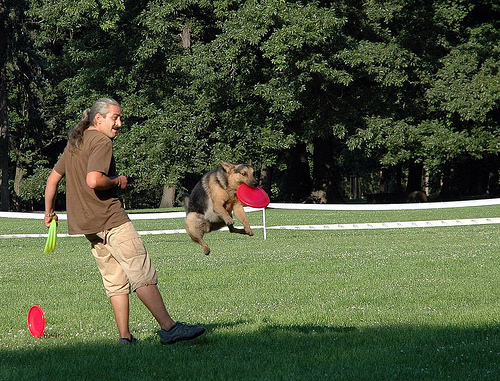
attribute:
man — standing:
[71, 83, 155, 343]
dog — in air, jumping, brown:
[162, 151, 281, 234]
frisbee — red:
[232, 172, 261, 232]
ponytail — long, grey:
[57, 105, 96, 143]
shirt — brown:
[57, 114, 136, 256]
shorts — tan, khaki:
[81, 216, 139, 314]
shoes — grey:
[119, 308, 203, 341]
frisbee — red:
[29, 301, 40, 342]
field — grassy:
[320, 243, 497, 379]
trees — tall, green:
[22, 6, 492, 195]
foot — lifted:
[155, 317, 219, 346]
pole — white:
[255, 214, 284, 256]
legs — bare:
[98, 289, 180, 330]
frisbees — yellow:
[39, 207, 65, 264]